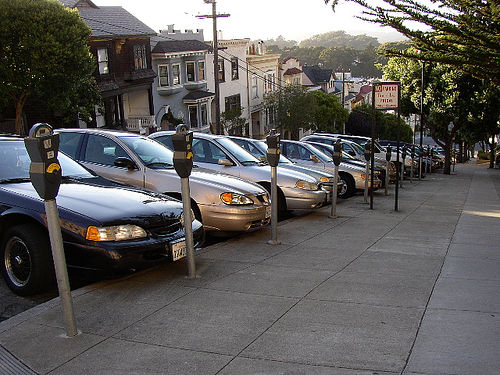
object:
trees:
[323, 0, 500, 178]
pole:
[195, 0, 231, 135]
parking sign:
[371, 81, 400, 111]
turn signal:
[85, 225, 101, 242]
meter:
[23, 122, 86, 337]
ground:
[0, 154, 500, 375]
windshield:
[209, 135, 263, 167]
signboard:
[371, 81, 401, 110]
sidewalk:
[0, 155, 499, 375]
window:
[1, 140, 93, 183]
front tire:
[0, 216, 49, 297]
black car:
[0, 133, 205, 297]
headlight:
[85, 223, 149, 243]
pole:
[368, 83, 377, 211]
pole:
[393, 106, 401, 211]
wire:
[75, 14, 290, 95]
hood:
[0, 174, 187, 229]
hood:
[160, 164, 267, 196]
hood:
[260, 164, 318, 188]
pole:
[341, 71, 346, 133]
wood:
[214, 77, 223, 106]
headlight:
[218, 191, 257, 208]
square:
[112, 289, 299, 354]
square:
[0, 318, 104, 375]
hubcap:
[4, 236, 29, 286]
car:
[105, 129, 328, 217]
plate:
[171, 241, 189, 262]